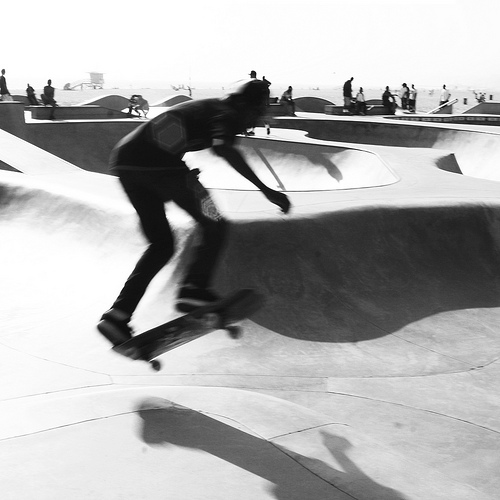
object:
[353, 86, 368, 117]
person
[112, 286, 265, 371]
skateboard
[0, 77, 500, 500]
skatepark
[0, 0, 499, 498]
air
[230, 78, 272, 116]
hat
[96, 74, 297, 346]
skateboarder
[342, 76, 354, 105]
people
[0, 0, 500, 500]
day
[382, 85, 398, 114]
skaters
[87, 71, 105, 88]
hut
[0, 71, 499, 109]
beach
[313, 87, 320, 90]
can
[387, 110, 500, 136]
rail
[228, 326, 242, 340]
wheel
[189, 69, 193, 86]
tower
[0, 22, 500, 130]
distance